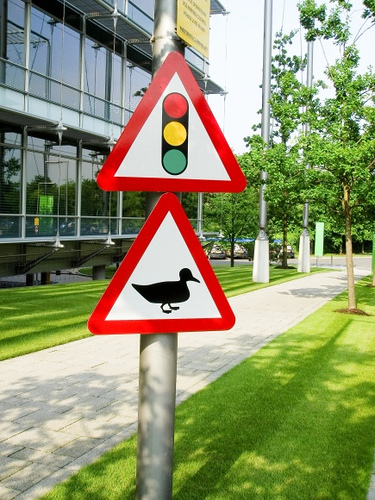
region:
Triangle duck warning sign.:
[68, 191, 243, 351]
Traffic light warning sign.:
[93, 50, 252, 210]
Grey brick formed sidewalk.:
[0, 261, 287, 409]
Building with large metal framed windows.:
[10, 5, 127, 262]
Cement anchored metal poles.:
[256, 3, 326, 292]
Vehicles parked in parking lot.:
[198, 220, 298, 273]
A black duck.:
[130, 267, 201, 314]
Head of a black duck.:
[178, 268, 193, 281]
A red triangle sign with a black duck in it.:
[84, 193, 236, 334]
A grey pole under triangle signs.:
[138, 332, 178, 498]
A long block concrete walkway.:
[0, 268, 372, 498]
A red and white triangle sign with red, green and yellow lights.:
[95, 50, 244, 191]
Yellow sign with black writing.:
[175, 2, 209, 60]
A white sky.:
[212, 2, 373, 149]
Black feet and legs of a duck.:
[160, 303, 179, 314]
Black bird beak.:
[191, 276, 200, 284]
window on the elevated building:
[0, 121, 20, 235]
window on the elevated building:
[27, 128, 75, 236]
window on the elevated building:
[81, 141, 116, 233]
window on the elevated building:
[5, 1, 25, 91]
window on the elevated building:
[27, 0, 78, 111]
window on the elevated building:
[83, 23, 121, 125]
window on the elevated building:
[123, 47, 150, 126]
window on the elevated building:
[126, 0, 154, 36]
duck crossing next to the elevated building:
[85, 194, 234, 330]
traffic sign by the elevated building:
[95, 52, 248, 192]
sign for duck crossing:
[72, 190, 241, 348]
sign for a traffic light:
[80, 43, 251, 189]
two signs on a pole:
[88, 44, 246, 333]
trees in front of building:
[256, 51, 372, 319]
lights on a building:
[49, 118, 67, 148]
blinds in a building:
[8, 148, 95, 227]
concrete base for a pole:
[248, 231, 275, 285]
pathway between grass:
[20, 342, 149, 433]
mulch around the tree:
[334, 301, 367, 319]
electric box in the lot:
[312, 216, 328, 267]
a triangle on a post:
[81, 190, 240, 338]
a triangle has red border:
[77, 193, 245, 339]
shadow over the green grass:
[249, 300, 371, 457]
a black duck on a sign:
[79, 192, 244, 342]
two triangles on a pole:
[81, 44, 253, 352]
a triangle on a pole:
[87, 44, 249, 198]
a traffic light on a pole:
[155, 87, 197, 180]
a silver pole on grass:
[130, 1, 188, 498]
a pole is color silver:
[247, 0, 277, 291]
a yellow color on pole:
[151, 0, 217, 65]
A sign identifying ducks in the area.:
[87, 190, 234, 329]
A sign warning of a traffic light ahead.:
[93, 49, 246, 191]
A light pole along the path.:
[250, 0, 276, 285]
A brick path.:
[0, 332, 137, 498]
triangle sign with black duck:
[84, 190, 236, 333]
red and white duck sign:
[74, 189, 248, 347]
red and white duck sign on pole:
[82, 192, 250, 449]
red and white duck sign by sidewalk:
[77, 191, 255, 470]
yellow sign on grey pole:
[147, 2, 217, 65]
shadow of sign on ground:
[133, 293, 362, 493]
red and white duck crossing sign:
[83, 189, 249, 348]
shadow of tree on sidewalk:
[276, 267, 349, 314]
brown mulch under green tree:
[331, 167, 366, 320]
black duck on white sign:
[123, 254, 205, 322]